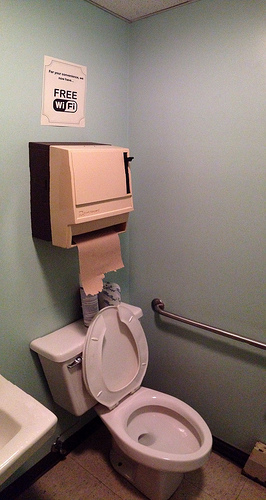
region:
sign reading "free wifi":
[41, 54, 87, 125]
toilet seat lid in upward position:
[83, 306, 149, 407]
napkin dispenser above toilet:
[27, 139, 132, 293]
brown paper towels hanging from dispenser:
[71, 226, 123, 293]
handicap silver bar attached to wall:
[152, 296, 264, 357]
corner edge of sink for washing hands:
[0, 371, 58, 484]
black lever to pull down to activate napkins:
[123, 148, 134, 197]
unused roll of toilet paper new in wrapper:
[79, 270, 121, 325]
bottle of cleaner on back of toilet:
[77, 270, 100, 325]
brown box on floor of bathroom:
[241, 438, 264, 481]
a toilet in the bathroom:
[83, 303, 216, 499]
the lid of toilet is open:
[80, 301, 216, 497]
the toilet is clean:
[107, 391, 214, 463]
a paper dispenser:
[23, 132, 145, 268]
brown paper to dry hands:
[71, 235, 130, 299]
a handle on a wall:
[150, 293, 264, 370]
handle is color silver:
[145, 296, 265, 350]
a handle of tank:
[65, 354, 84, 376]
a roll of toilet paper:
[98, 271, 145, 323]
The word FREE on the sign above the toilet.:
[53, 85, 78, 97]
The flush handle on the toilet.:
[64, 359, 82, 368]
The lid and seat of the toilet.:
[88, 308, 146, 399]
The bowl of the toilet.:
[104, 399, 211, 470]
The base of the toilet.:
[109, 461, 185, 499]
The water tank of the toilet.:
[42, 351, 98, 414]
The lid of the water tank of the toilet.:
[30, 318, 80, 361]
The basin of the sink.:
[0, 375, 57, 482]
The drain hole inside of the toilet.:
[141, 434, 156, 445]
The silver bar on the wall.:
[155, 302, 265, 349]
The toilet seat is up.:
[88, 333, 147, 393]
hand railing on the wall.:
[155, 299, 252, 335]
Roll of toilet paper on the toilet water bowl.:
[77, 288, 122, 308]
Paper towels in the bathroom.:
[73, 236, 132, 280]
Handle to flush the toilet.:
[71, 358, 80, 371]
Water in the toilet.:
[138, 422, 186, 445]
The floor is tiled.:
[63, 456, 106, 487]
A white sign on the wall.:
[33, 55, 108, 113]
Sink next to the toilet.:
[7, 370, 56, 447]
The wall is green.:
[142, 99, 255, 257]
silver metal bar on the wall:
[151, 293, 261, 347]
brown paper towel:
[76, 232, 126, 268]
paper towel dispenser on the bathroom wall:
[25, 138, 135, 247]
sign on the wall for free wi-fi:
[40, 54, 86, 127]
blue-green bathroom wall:
[135, 21, 263, 220]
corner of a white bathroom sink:
[2, 405, 58, 437]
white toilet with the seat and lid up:
[40, 309, 212, 492]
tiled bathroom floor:
[56, 466, 104, 497]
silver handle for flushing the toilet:
[67, 356, 81, 368]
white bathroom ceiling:
[114, 2, 150, 10]